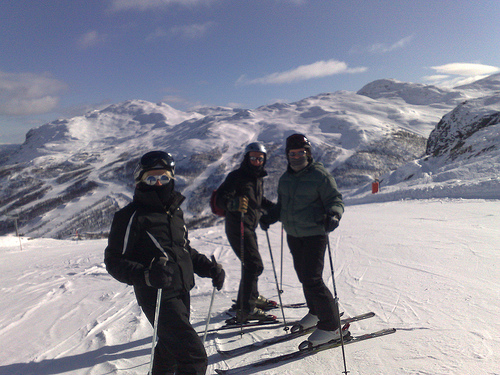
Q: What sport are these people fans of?
A: Skiing.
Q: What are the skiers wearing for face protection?
A: Goggles.and high collars.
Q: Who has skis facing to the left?
A: A man in a grey parka, wearing white ski boots.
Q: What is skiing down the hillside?
A: The person.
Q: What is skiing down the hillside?
A: The person.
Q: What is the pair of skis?
A: Gray.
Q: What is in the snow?
A: Ski tracks.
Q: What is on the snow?
A: The shadow of the skier.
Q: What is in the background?
A: The mountain.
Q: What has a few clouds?
A: The blue sky.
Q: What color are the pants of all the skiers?
A: Black.